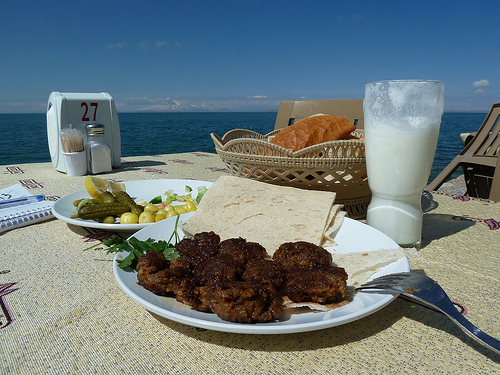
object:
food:
[284, 266, 349, 305]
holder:
[45, 91, 122, 173]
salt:
[83, 121, 113, 174]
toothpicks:
[60, 136, 66, 152]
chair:
[424, 101, 500, 200]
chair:
[272, 98, 364, 130]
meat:
[272, 240, 333, 272]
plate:
[49, 178, 232, 235]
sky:
[0, 0, 497, 112]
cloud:
[471, 78, 493, 89]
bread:
[181, 175, 338, 264]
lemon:
[85, 175, 127, 198]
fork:
[353, 270, 498, 358]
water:
[0, 112, 497, 177]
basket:
[209, 113, 370, 219]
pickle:
[114, 190, 140, 215]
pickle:
[78, 202, 143, 217]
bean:
[120, 212, 138, 224]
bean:
[139, 211, 155, 224]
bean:
[144, 203, 159, 211]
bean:
[166, 210, 178, 218]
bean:
[164, 204, 174, 211]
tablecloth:
[0, 149, 500, 375]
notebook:
[0, 183, 58, 234]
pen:
[0, 193, 44, 207]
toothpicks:
[72, 134, 75, 152]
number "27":
[81, 102, 99, 122]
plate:
[113, 207, 409, 336]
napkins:
[46, 104, 58, 156]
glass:
[360, 74, 446, 252]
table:
[0, 150, 500, 373]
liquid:
[365, 114, 438, 244]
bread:
[241, 114, 357, 178]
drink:
[364, 116, 439, 244]